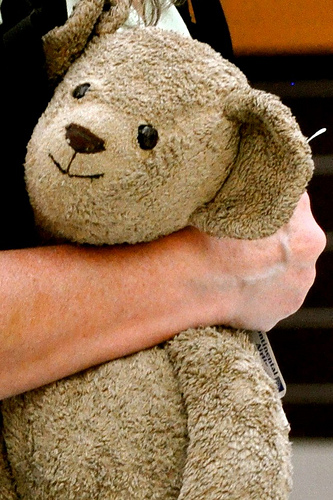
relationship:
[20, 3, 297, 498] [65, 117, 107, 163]
bear has nose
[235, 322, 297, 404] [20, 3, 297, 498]
tag on bear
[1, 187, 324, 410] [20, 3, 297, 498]
arm around bear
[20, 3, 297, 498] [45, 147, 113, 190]
bear has mouth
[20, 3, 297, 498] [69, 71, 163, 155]
bear has eyes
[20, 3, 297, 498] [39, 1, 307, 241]
bear has ears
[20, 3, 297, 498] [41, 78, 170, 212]
bear has face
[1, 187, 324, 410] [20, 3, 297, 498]
arm holding bear